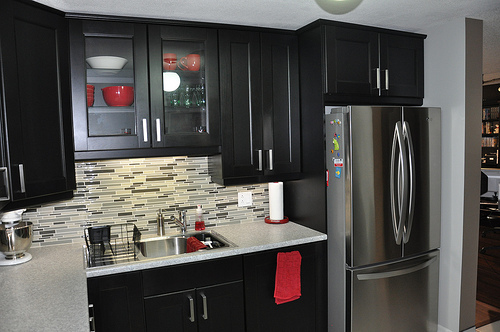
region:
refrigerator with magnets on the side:
[325, 103, 440, 328]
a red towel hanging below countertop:
[271, 250, 298, 300]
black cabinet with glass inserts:
[70, 16, 217, 158]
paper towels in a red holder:
[262, 180, 287, 222]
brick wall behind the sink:
[22, 155, 267, 245]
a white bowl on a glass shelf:
[85, 52, 125, 72]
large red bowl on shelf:
[100, 85, 131, 105]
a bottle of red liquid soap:
[192, 202, 203, 228]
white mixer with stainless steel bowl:
[0, 205, 31, 262]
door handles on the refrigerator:
[390, 120, 416, 245]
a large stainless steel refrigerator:
[331, 100, 455, 330]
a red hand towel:
[266, 248, 311, 304]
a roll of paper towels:
[266, 181, 291, 218]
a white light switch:
[231, 190, 256, 207]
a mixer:
[0, 209, 39, 266]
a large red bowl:
[102, 82, 134, 107]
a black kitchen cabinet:
[217, 34, 268, 181]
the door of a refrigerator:
[393, 123, 408, 246]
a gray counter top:
[212, 217, 328, 247]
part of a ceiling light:
[317, 0, 364, 17]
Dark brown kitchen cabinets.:
[0, 3, 425, 328]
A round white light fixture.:
[305, 0, 371, 15]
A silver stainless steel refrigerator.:
[325, 106, 435, 326]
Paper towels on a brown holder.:
[265, 177, 286, 222]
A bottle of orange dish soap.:
[190, 205, 210, 232]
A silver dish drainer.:
[75, 220, 145, 264]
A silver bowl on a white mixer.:
[0, 206, 30, 261]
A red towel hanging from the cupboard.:
[272, 250, 302, 305]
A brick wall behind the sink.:
[15, 157, 276, 246]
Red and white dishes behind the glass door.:
[78, 31, 204, 141]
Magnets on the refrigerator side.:
[325, 114, 350, 187]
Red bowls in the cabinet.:
[89, 85, 151, 111]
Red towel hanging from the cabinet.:
[266, 244, 309, 306]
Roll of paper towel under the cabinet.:
[262, 180, 289, 229]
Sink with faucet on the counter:
[133, 208, 222, 265]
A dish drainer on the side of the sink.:
[73, 215, 145, 267]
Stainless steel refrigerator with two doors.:
[340, 109, 442, 274]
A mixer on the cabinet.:
[8, 218, 38, 261]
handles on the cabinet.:
[250, 128, 278, 175]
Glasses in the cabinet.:
[159, 72, 214, 111]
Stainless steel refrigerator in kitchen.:
[327, 100, 448, 330]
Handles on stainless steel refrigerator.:
[390, 119, 420, 245]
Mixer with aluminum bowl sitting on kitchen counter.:
[1, 207, 37, 265]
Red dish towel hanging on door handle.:
[269, 248, 310, 308]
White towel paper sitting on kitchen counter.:
[262, 180, 292, 227]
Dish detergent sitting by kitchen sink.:
[191, 199, 209, 235]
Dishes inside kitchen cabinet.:
[72, 17, 222, 153]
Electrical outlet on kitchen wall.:
[231, 187, 257, 212]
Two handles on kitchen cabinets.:
[185, 289, 212, 323]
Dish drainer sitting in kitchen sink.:
[81, 218, 143, 268]